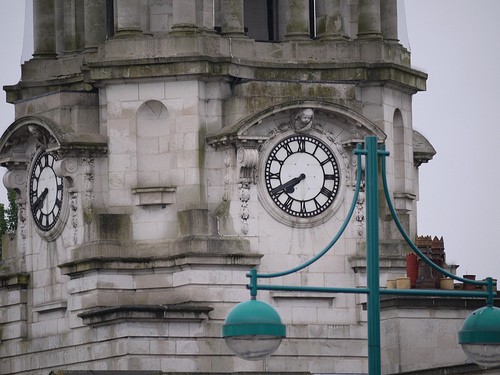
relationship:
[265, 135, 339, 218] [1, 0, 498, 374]
clock on building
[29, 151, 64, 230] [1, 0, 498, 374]
clock on building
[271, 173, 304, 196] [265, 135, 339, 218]
hands on clock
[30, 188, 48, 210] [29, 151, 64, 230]
hands on clock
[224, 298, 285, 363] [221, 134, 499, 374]
light on light fixture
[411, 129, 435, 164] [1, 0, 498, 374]
overhang on building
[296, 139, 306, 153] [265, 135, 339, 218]
number on clock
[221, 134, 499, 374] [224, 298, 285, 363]
light fixture has light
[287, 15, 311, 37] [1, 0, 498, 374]
moss on building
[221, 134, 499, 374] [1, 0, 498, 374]
light fixture in front of building